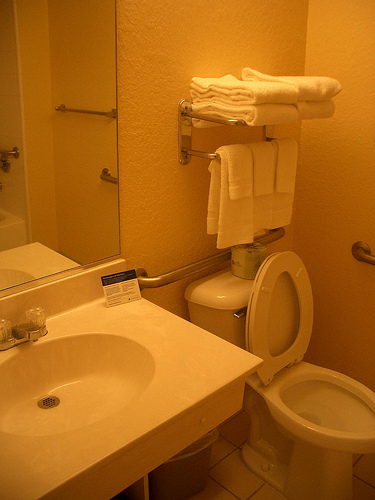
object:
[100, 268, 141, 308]
sign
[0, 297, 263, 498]
counter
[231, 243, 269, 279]
tissue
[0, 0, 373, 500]
toilet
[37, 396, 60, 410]
drain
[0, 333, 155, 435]
sink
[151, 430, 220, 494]
can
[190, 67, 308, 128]
towel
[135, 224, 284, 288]
handle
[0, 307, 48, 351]
fuacet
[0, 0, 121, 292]
mirror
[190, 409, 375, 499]
floor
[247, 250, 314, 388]
seat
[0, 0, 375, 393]
wall